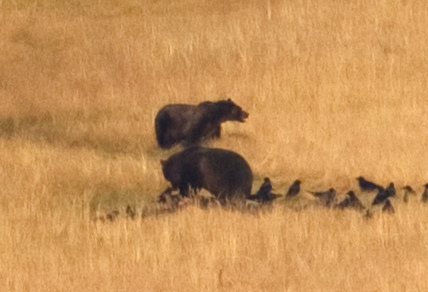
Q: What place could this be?
A: It is a field.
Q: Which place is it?
A: It is a field.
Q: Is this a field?
A: Yes, it is a field.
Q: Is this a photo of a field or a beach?
A: It is showing a field.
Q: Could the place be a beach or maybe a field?
A: It is a field.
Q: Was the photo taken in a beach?
A: No, the picture was taken in a field.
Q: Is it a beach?
A: No, it is a field.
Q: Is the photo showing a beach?
A: No, the picture is showing a field.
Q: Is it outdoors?
A: Yes, it is outdoors.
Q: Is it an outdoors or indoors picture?
A: It is outdoors.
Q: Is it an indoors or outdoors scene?
A: It is outdoors.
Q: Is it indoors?
A: No, it is outdoors.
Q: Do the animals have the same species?
A: No, there are both birds and bears.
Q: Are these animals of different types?
A: Yes, they are birds and bears.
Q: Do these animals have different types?
A: Yes, they are birds and bears.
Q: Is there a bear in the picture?
A: Yes, there is a bear.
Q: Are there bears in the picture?
A: Yes, there is a bear.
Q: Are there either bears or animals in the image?
A: Yes, there is a bear.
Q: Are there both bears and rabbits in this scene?
A: No, there is a bear but no rabbits.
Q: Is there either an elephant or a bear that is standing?
A: Yes, the bear is standing.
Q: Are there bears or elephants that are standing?
A: Yes, the bear is standing.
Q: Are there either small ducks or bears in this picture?
A: Yes, there is a small bear.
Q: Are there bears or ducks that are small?
A: Yes, the bear is small.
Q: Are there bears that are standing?
A: Yes, there is a bear that is standing.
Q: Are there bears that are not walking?
A: Yes, there is a bear that is standing.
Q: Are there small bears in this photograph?
A: Yes, there is a small bear.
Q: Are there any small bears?
A: Yes, there is a small bear.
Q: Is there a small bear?
A: Yes, there is a small bear.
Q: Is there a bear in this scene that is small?
A: Yes, there is a bear that is small.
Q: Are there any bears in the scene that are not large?
A: Yes, there is a small bear.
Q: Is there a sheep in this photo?
A: No, there is no sheep.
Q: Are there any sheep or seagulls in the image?
A: No, there are no sheep or seagulls.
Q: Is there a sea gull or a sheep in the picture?
A: No, there are no sheep or seagulls.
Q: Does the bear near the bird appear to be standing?
A: Yes, the bear is standing.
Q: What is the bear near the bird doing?
A: The bear is standing.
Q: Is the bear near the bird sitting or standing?
A: The bear is standing.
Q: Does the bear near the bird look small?
A: Yes, the bear is small.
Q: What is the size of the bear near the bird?
A: The bear is small.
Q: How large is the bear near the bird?
A: The bear is small.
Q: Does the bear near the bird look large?
A: No, the bear is small.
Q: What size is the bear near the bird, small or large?
A: The bear is small.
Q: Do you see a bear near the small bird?
A: Yes, there is a bear near the bird.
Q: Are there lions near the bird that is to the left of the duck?
A: No, there is a bear near the bird.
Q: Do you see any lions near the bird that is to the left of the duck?
A: No, there is a bear near the bird.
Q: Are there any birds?
A: Yes, there is a bird.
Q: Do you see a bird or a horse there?
A: Yes, there is a bird.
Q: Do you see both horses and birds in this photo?
A: No, there is a bird but no horses.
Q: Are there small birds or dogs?
A: Yes, there is a small bird.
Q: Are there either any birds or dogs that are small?
A: Yes, the bird is small.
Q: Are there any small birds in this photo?
A: Yes, there is a small bird.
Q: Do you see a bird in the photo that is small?
A: Yes, there is a small bird.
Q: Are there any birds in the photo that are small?
A: Yes, there is a bird that is small.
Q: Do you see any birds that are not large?
A: Yes, there is a small bird.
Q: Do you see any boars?
A: No, there are no boars.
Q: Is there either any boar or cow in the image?
A: No, there are no boars or cows.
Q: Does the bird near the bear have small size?
A: Yes, the bird is small.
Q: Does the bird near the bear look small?
A: Yes, the bird is small.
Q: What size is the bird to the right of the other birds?
A: The bird is small.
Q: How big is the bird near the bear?
A: The bird is small.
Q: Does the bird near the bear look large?
A: No, the bird is small.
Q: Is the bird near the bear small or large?
A: The bird is small.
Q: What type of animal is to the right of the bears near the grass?
A: The animal is a bird.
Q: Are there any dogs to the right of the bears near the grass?
A: No, there is a bird to the right of the bears.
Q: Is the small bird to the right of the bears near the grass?
A: Yes, the bird is to the right of the bears.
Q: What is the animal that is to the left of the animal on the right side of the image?
A: The animal is a bird.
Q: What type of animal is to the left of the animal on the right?
A: The animal is a bird.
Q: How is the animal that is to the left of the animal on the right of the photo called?
A: The animal is a bird.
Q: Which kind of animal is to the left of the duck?
A: The animal is a bird.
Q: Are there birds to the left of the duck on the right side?
A: Yes, there is a bird to the left of the duck.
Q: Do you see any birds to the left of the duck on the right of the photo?
A: Yes, there is a bird to the left of the duck.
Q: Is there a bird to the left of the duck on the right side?
A: Yes, there is a bird to the left of the duck.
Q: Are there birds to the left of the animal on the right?
A: Yes, there is a bird to the left of the duck.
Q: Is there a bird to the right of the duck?
A: No, the bird is to the left of the duck.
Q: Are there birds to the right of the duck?
A: No, the bird is to the left of the duck.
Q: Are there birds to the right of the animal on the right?
A: No, the bird is to the left of the duck.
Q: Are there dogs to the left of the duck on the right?
A: No, there is a bird to the left of the duck.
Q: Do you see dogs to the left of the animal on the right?
A: No, there is a bird to the left of the duck.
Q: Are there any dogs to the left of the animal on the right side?
A: No, there is a bird to the left of the duck.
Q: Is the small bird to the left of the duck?
A: Yes, the bird is to the left of the duck.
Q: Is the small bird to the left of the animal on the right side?
A: Yes, the bird is to the left of the duck.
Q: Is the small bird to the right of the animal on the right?
A: No, the bird is to the left of the duck.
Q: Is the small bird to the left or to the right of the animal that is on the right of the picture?
A: The bird is to the left of the duck.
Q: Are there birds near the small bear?
A: Yes, there is a bird near the bear.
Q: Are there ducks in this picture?
A: Yes, there is a duck.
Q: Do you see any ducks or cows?
A: Yes, there is a duck.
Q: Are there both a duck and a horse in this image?
A: No, there is a duck but no horses.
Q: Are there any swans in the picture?
A: No, there are no swans.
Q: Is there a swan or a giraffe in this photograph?
A: No, there are no swans or giraffes.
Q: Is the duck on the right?
A: Yes, the duck is on the right of the image.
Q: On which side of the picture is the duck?
A: The duck is on the right of the image.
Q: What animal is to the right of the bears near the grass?
A: The animal is a duck.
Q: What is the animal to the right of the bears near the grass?
A: The animal is a duck.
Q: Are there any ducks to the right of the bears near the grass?
A: Yes, there is a duck to the right of the bears.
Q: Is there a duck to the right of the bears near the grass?
A: Yes, there is a duck to the right of the bears.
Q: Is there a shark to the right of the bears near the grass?
A: No, there is a duck to the right of the bears.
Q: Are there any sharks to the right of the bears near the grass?
A: No, there is a duck to the right of the bears.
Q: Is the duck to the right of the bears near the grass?
A: Yes, the duck is to the right of the bears.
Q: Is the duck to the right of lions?
A: No, the duck is to the right of the bears.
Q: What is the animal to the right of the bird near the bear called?
A: The animal is a duck.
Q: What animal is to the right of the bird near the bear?
A: The animal is a duck.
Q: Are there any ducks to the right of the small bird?
A: Yes, there is a duck to the right of the bird.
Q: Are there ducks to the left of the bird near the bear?
A: No, the duck is to the right of the bird.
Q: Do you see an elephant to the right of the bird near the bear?
A: No, there is a duck to the right of the bird.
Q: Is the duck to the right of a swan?
A: No, the duck is to the right of the bird.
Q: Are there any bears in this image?
A: Yes, there are bears.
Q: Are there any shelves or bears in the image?
A: Yes, there are bears.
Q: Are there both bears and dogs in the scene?
A: No, there are bears but no dogs.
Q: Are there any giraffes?
A: No, there are no giraffes.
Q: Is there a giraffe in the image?
A: No, there are no giraffes.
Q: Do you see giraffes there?
A: No, there are no giraffes.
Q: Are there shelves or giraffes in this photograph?
A: No, there are no giraffes or shelves.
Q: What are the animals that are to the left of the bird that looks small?
A: The animals are bears.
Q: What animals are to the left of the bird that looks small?
A: The animals are bears.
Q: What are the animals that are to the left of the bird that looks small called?
A: The animals are bears.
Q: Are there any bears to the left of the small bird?
A: Yes, there are bears to the left of the bird.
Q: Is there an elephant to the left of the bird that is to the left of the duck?
A: No, there are bears to the left of the bird.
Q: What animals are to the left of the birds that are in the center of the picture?
A: The animals are bears.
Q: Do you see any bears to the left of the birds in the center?
A: Yes, there are bears to the left of the birds.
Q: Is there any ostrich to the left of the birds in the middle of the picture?
A: No, there are bears to the left of the birds.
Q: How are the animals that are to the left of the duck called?
A: The animals are bears.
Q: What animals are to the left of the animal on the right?
A: The animals are bears.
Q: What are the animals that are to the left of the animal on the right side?
A: The animals are bears.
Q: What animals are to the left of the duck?
A: The animals are bears.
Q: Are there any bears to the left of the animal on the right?
A: Yes, there are bears to the left of the duck.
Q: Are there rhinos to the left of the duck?
A: No, there are bears to the left of the duck.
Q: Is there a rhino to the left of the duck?
A: No, there are bears to the left of the duck.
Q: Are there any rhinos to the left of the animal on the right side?
A: No, there are bears to the left of the duck.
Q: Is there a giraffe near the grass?
A: No, there are bears near the grass.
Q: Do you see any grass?
A: Yes, there is grass.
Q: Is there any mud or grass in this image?
A: Yes, there is grass.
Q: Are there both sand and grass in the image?
A: No, there is grass but no sand.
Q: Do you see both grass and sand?
A: No, there is grass but no sand.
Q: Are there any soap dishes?
A: No, there are no soap dishes.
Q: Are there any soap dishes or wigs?
A: No, there are no soap dishes or wigs.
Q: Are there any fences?
A: No, there are no fences.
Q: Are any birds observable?
A: Yes, there are birds.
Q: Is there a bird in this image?
A: Yes, there are birds.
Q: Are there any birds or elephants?
A: Yes, there are birds.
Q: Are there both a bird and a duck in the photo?
A: Yes, there are both a bird and a duck.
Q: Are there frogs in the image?
A: No, there are no frogs.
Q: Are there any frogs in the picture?
A: No, there are no frogs.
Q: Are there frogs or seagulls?
A: No, there are no frogs or seagulls.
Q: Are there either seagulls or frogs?
A: No, there are no frogs or seagulls.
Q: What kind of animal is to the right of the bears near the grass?
A: The animals are birds.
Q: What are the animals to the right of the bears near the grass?
A: The animals are birds.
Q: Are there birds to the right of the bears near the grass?
A: Yes, there are birds to the right of the bears.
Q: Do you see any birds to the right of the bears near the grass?
A: Yes, there are birds to the right of the bears.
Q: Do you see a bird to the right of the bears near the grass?
A: Yes, there are birds to the right of the bears.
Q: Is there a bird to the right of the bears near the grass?
A: Yes, there are birds to the right of the bears.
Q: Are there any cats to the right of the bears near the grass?
A: No, there are birds to the right of the bears.